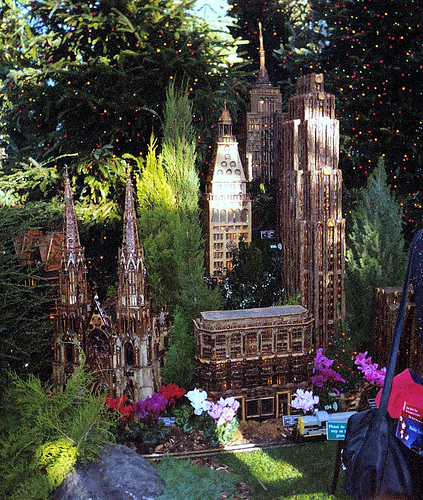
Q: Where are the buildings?
A: Display.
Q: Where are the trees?
A: Beside buildings.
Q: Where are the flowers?
A: In front of building.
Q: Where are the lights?
A: On trees.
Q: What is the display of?
A: Building.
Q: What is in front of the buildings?
A: Flowers.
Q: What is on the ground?
A: Flower.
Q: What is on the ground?
A: Flower.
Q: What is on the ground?
A: Flower.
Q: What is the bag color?
A: Black.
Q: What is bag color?
A: Black.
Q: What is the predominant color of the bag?
A: Black.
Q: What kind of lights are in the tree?
A: Christmas lights.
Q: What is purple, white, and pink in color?
A: Flowers.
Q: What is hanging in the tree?
A: Colorful beads.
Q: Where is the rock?
A: By the flowers.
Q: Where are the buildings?
A: In the trees.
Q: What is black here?
A: A purse.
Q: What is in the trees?
A: Lights.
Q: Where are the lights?
A: In the trees.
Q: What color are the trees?
A: Green.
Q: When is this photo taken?
A: In the daytime.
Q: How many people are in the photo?
A: Zero.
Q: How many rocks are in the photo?
A: One.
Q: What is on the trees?
A: Lights.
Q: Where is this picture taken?
A: Model city area.